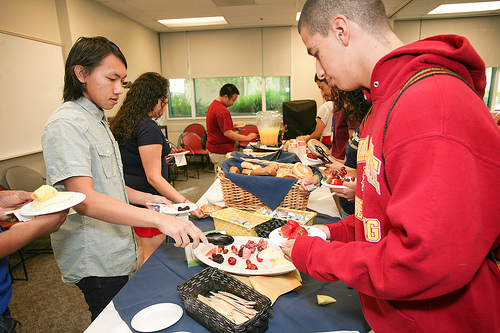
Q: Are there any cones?
A: No, there are no cones.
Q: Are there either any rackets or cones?
A: No, there are no cones or rackets.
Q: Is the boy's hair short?
A: No, the hair is long.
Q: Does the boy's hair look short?
A: No, the hair is long.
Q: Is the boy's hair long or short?
A: The hair is long.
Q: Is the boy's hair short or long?
A: The hair is long.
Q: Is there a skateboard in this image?
A: No, there are no skateboards.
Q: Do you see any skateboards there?
A: No, there are no skateboards.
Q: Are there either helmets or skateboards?
A: No, there are no skateboards or helmets.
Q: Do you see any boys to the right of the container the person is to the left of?
A: Yes, there is a boy to the right of the container.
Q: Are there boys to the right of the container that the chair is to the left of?
A: Yes, there is a boy to the right of the container.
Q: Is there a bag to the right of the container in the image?
A: No, there is a boy to the right of the container.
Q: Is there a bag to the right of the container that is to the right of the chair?
A: No, there is a boy to the right of the container.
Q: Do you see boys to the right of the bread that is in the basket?
A: Yes, there is a boy to the right of the bread.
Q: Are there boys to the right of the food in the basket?
A: Yes, there is a boy to the right of the bread.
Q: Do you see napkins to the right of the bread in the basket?
A: No, there is a boy to the right of the bread.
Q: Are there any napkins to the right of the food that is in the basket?
A: No, there is a boy to the right of the bread.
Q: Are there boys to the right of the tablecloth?
A: Yes, there is a boy to the right of the tablecloth.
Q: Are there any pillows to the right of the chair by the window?
A: No, there is a boy to the right of the chair.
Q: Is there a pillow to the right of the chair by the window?
A: No, there is a boy to the right of the chair.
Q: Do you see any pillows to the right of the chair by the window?
A: No, there is a boy to the right of the chair.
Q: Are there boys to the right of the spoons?
A: Yes, there is a boy to the right of the spoons.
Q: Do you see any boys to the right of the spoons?
A: Yes, there is a boy to the right of the spoons.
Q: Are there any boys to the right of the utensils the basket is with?
A: Yes, there is a boy to the right of the spoons.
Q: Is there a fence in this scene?
A: No, there are no fences.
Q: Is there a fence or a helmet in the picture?
A: No, there are no fences or helmets.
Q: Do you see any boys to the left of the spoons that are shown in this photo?
A: Yes, there is a boy to the left of the spoons.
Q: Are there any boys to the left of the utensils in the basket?
A: Yes, there is a boy to the left of the spoons.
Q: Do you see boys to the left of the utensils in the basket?
A: Yes, there is a boy to the left of the spoons.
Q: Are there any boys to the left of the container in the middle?
A: Yes, there is a boy to the left of the container.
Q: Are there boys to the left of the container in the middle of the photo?
A: Yes, there is a boy to the left of the container.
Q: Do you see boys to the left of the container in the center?
A: Yes, there is a boy to the left of the container.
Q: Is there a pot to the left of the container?
A: No, there is a boy to the left of the container.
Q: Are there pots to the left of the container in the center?
A: No, there is a boy to the left of the container.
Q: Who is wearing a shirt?
A: The boy is wearing a shirt.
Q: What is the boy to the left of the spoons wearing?
A: The boy is wearing a shirt.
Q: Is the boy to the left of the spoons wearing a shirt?
A: Yes, the boy is wearing a shirt.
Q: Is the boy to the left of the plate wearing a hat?
A: No, the boy is wearing a shirt.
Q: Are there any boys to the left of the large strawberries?
A: Yes, there is a boy to the left of the strawberries.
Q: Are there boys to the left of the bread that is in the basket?
A: Yes, there is a boy to the left of the bread.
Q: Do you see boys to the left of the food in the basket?
A: Yes, there is a boy to the left of the bread.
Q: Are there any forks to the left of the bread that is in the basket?
A: No, there is a boy to the left of the bread.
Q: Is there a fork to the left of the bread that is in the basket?
A: No, there is a boy to the left of the bread.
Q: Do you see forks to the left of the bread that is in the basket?
A: No, there is a boy to the left of the bread.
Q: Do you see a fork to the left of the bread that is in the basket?
A: No, there is a boy to the left of the bread.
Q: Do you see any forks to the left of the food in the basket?
A: No, there is a boy to the left of the bread.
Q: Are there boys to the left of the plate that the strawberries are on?
A: Yes, there is a boy to the left of the plate.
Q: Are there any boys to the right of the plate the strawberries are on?
A: No, the boy is to the left of the plate.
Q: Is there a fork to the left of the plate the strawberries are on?
A: No, there is a boy to the left of the plate.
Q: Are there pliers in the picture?
A: No, there are no pliers.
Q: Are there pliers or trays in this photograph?
A: No, there are no pliers or trays.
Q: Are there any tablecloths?
A: Yes, there is a tablecloth.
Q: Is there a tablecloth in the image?
A: Yes, there is a tablecloth.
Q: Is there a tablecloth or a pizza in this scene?
A: Yes, there is a tablecloth.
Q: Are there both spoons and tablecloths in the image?
A: Yes, there are both a tablecloth and a spoon.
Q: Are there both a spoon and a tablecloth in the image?
A: Yes, there are both a tablecloth and a spoon.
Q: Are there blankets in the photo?
A: No, there are no blankets.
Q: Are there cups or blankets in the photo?
A: No, there are no blankets or cups.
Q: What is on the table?
A: The table cloth is on the table.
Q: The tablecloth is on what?
A: The tablecloth is on the table.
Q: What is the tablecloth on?
A: The tablecloth is on the table.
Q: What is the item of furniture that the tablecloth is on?
A: The piece of furniture is a table.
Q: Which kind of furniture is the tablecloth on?
A: The tablecloth is on the table.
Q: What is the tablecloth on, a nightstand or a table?
A: The tablecloth is on a table.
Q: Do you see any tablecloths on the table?
A: Yes, there is a tablecloth on the table.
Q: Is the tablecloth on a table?
A: Yes, the tablecloth is on a table.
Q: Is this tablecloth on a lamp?
A: No, the tablecloth is on a table.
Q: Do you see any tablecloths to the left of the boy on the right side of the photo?
A: Yes, there is a tablecloth to the left of the boy.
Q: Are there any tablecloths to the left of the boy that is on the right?
A: Yes, there is a tablecloth to the left of the boy.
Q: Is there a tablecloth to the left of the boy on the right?
A: Yes, there is a tablecloth to the left of the boy.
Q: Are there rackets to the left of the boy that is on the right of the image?
A: No, there is a tablecloth to the left of the boy.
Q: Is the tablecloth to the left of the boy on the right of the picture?
A: Yes, the tablecloth is to the left of the boy.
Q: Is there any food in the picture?
A: Yes, there is food.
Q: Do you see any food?
A: Yes, there is food.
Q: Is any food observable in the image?
A: Yes, there is food.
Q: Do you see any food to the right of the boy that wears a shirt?
A: Yes, there is food to the right of the boy.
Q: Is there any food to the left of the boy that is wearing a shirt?
A: No, the food is to the right of the boy.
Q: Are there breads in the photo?
A: Yes, there is a bread.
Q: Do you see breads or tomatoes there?
A: Yes, there is a bread.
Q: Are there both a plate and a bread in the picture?
A: Yes, there are both a bread and a plate.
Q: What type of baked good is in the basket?
A: The food is a bread.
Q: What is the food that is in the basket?
A: The food is a bread.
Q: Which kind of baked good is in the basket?
A: The food is a bread.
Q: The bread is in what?
A: The bread is in the basket.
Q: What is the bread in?
A: The bread is in the basket.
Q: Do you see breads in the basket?
A: Yes, there is a bread in the basket.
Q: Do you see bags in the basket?
A: No, there is a bread in the basket.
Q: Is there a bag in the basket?
A: No, there is a bread in the basket.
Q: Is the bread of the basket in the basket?
A: Yes, the bread is in the basket.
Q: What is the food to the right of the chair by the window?
A: The food is a bread.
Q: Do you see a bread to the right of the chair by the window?
A: Yes, there is a bread to the right of the chair.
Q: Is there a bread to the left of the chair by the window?
A: No, the bread is to the right of the chair.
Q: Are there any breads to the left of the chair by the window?
A: No, the bread is to the right of the chair.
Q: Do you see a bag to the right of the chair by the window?
A: No, there is a bread to the right of the chair.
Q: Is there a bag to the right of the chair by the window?
A: No, there is a bread to the right of the chair.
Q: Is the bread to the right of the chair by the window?
A: Yes, the bread is to the right of the chair.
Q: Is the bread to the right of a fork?
A: No, the bread is to the right of the chair.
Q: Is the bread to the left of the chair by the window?
A: No, the bread is to the right of the chair.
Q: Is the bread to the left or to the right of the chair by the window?
A: The bread is to the right of the chair.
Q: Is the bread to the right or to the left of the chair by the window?
A: The bread is to the right of the chair.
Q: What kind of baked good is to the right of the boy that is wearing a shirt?
A: The food is a bread.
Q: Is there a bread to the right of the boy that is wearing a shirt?
A: Yes, there is a bread to the right of the boy.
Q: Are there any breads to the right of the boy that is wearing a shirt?
A: Yes, there is a bread to the right of the boy.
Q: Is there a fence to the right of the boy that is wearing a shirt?
A: No, there is a bread to the right of the boy.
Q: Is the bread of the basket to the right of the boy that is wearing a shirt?
A: Yes, the bread is to the right of the boy.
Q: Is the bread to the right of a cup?
A: No, the bread is to the right of the boy.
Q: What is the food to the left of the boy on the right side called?
A: The food is a bread.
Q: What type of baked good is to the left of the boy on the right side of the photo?
A: The food is a bread.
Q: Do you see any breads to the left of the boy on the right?
A: Yes, there is a bread to the left of the boy.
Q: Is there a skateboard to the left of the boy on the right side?
A: No, there is a bread to the left of the boy.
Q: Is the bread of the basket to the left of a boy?
A: Yes, the bread is to the left of a boy.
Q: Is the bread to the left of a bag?
A: No, the bread is to the left of a boy.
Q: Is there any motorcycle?
A: No, there are no motorcycles.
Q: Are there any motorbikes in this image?
A: No, there are no motorbikes.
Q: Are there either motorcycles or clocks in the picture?
A: No, there are no motorcycles or clocks.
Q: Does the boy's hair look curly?
A: Yes, the hair is curly.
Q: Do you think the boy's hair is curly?
A: Yes, the hair is curly.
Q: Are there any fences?
A: No, there are no fences.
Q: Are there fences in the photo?
A: No, there are no fences.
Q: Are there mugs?
A: No, there are no mugs.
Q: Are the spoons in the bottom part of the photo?
A: Yes, the spoons are in the bottom of the image.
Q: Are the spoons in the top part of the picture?
A: No, the spoons are in the bottom of the image.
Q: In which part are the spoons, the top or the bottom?
A: The spoons are in the bottom of the image.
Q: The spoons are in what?
A: The spoons are in the basket.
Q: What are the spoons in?
A: The spoons are in the basket.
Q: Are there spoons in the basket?
A: Yes, there are spoons in the basket.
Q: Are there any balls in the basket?
A: No, there are spoons in the basket.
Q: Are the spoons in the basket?
A: Yes, the spoons are in the basket.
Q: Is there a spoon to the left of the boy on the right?
A: Yes, there are spoons to the left of the boy.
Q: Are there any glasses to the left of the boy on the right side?
A: No, there are spoons to the left of the boy.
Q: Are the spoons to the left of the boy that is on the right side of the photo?
A: Yes, the spoons are to the left of the boy.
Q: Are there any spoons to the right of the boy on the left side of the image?
A: Yes, there are spoons to the right of the boy.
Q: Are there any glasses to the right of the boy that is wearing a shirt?
A: No, there are spoons to the right of the boy.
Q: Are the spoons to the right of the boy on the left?
A: Yes, the spoons are to the right of the boy.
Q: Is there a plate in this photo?
A: Yes, there is a plate.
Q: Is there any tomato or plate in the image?
A: Yes, there is a plate.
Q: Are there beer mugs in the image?
A: No, there are no beer mugs.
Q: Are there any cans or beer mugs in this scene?
A: No, there are no beer mugs or cans.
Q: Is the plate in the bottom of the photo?
A: Yes, the plate is in the bottom of the image.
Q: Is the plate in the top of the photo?
A: No, the plate is in the bottom of the image.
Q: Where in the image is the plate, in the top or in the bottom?
A: The plate is in the bottom of the image.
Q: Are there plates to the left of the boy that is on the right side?
A: Yes, there is a plate to the left of the boy.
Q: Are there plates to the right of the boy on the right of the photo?
A: No, the plate is to the left of the boy.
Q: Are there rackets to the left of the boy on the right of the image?
A: No, there is a plate to the left of the boy.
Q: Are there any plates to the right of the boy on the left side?
A: Yes, there is a plate to the right of the boy.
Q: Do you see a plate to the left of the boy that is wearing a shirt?
A: No, the plate is to the right of the boy.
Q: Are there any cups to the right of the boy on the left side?
A: No, there is a plate to the right of the boy.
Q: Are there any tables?
A: Yes, there is a table.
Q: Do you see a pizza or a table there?
A: Yes, there is a table.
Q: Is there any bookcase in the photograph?
A: No, there are no bookcases.